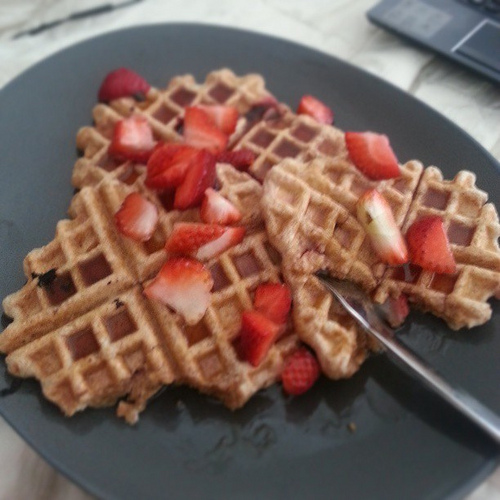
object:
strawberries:
[163, 218, 245, 266]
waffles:
[259, 130, 499, 381]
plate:
[0, 21, 498, 498]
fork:
[312, 273, 499, 444]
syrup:
[159, 412, 358, 467]